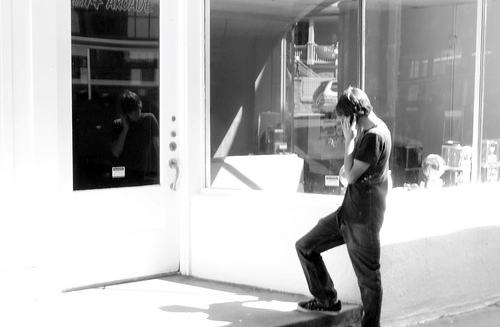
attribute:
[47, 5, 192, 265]
door — closed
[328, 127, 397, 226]
teeshirt — black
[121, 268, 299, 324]
ground — paved